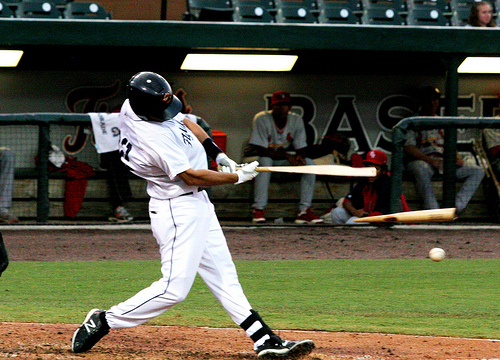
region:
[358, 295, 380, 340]
part of a field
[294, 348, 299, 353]
part of a shoe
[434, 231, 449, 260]
part of a ball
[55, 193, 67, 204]
part of a fence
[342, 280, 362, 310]
edge of a lawn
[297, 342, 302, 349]
part of a shoe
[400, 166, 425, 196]
edge of a pole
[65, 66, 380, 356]
man holding a bat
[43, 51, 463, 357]
man hitting a ball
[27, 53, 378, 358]
man wearing a black helmet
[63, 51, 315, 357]
man wearing white shirt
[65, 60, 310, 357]
man wearing white pants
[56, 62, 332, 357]
man wearing black shoes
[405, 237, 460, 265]
base ball in the air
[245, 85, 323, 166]
man wearing red cap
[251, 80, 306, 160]
man sitting down on bench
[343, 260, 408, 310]
green grass in field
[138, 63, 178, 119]
Person is wearing black helmet.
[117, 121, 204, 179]
Person is wearing white shirt.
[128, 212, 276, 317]
Person is wearing white pants.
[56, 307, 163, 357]
Person wearing black and white shoes.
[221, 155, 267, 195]
Person wearing white gloves.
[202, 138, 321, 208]
Person swinging baseball bat.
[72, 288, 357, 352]
Person standing in dirt.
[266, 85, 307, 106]
Person wearing red hat.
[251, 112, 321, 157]
Person wearing white shirt.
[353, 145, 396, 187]
Person wearing red hat.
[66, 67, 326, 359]
batter swinging at the baseball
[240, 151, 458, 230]
bat breaking in half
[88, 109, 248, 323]
white uniform of the batter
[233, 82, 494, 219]
players sitting in the dugout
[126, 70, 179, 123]
black helmt of the batter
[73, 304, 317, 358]
black and white cleats of the batter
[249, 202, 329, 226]
red and white cleats of player in dugout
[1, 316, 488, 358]
dirt in the batter's box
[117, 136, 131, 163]
black lettering on white jersey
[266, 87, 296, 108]
red hat of man in dugout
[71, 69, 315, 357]
A baseball player holding baseball bat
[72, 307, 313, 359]
Black shoes on the player's feet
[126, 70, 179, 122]
Black baseball helmet the player is wearing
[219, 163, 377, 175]
The baseball bat the batter is holding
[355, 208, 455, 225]
Broken peice of the baseball bat after hitting the ball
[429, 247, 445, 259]
Baseball responsible for breaking the bat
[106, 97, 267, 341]
White team uniform that the player is wearing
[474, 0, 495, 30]
One spectator in the gallery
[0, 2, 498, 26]
The stands for the spectators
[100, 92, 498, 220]
Other team players in the dugout